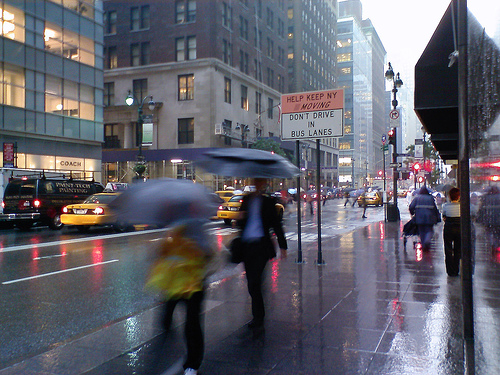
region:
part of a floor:
[323, 270, 365, 332]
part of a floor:
[321, 291, 352, 338]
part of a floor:
[359, 261, 379, 285]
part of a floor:
[336, 255, 371, 310]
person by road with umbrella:
[129, 170, 184, 355]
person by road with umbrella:
[238, 128, 295, 300]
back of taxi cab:
[65, 190, 120, 232]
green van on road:
[8, 167, 112, 220]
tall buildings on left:
[115, 17, 452, 154]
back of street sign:
[422, 14, 499, 249]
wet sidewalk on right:
[280, 287, 458, 372]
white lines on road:
[0, 236, 123, 301]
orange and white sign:
[272, 86, 378, 151]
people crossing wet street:
[307, 179, 397, 209]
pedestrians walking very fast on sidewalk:
[103, 147, 301, 374]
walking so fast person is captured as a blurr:
[107, 174, 222, 373]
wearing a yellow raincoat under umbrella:
[143, 223, 216, 373]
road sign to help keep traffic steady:
[279, 88, 346, 270]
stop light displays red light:
[405, 155, 423, 182]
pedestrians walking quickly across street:
[319, 176, 372, 221]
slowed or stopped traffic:
[3, 167, 280, 233]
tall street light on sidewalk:
[383, 56, 407, 221]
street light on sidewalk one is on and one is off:
[126, 86, 156, 183]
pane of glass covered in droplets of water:
[463, 2, 498, 373]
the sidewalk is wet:
[323, 265, 437, 373]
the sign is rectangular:
[276, 83, 356, 139]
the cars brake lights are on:
[57, 198, 104, 223]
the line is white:
[21, 266, 55, 287]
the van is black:
[3, 165, 63, 231]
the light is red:
[403, 160, 426, 177]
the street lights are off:
[380, 62, 404, 93]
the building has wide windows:
[37, 15, 96, 67]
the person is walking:
[403, 177, 440, 260]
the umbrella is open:
[201, 137, 308, 193]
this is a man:
[225, 158, 299, 330]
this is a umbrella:
[217, 149, 299, 188]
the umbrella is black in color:
[241, 150, 298, 179]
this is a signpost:
[281, 83, 336, 137]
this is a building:
[143, 26, 279, 125]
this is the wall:
[158, 23, 181, 71]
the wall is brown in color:
[142, 22, 164, 62]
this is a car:
[68, 198, 103, 233]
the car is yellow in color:
[72, 209, 93, 230]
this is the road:
[8, 245, 105, 344]